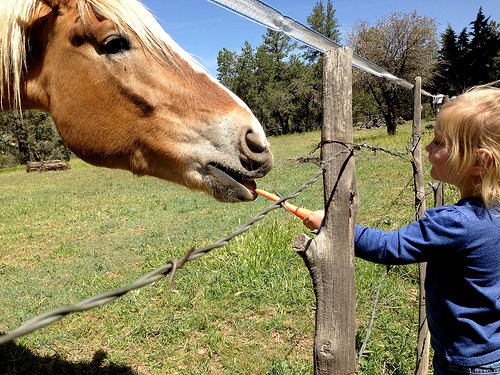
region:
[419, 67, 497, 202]
The girl has light hair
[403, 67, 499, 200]
The girls hair is blonde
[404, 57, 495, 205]
The girls hair is straight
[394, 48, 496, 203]
The girls hair is wind blown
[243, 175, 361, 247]
The girl is holding a carrot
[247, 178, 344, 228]
The carrot is orange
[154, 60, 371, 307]
The girl is feeding a horse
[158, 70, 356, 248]
Girl is feeding the horse a carrot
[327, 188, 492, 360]
The girls shirt is blue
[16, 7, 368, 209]
The horse is brown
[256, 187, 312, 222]
Stick of carrot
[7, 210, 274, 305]
Barbed wire of the fence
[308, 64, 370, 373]
Wooden fencing post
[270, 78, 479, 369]
Child holding out a carrot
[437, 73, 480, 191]
Blonde hair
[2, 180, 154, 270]
Grass covered ground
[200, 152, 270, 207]
Mouth of a horse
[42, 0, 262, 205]
Head of a horse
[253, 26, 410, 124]
Big trees in the background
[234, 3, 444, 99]
Long white ribbon on the fence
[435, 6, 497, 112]
Dark green trees on the far right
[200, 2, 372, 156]
Green evergreen trees in the center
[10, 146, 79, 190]
Dead log in the left of the pasture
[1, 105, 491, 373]
Green grassy pasture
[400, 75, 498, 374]
Little girl with blue shirt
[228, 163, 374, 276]
Carrot the little girl is feeding to the horse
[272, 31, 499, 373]
Wooden fence posts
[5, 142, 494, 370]
Barbed wire attached to the fence posts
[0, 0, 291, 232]
Horse taking the carrot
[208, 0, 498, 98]
Ribbon/tape on the top of the fence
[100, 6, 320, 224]
Horse nibbling on carrot.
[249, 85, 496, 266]
Girl feeding horse.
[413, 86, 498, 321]
Very young girl in blue shirt.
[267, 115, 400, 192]
Fence is made from wood and bobbed wire.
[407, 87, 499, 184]
Girl has blond hair.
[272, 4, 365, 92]
Blue and white strap lines the top of the fence.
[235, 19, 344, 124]
Trees are in the background.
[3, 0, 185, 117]
Horse has blond mane.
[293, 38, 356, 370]
Fence wood is full of knots and branch stubs.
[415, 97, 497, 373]
Girl is wearing blue jeans.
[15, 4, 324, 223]
Horse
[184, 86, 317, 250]
Horse is eating a carrot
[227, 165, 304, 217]
Orange carrot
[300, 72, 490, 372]
Shirt is blue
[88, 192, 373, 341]
Grass has not been cut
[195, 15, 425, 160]
Trees in the distance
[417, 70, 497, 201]
She is blonde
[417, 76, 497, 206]
Girl looking at horse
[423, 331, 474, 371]
Wearing jeans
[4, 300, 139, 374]
Shadow in the corner